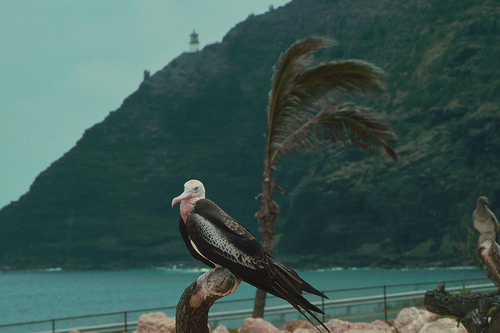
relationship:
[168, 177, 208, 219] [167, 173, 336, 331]
head on a bird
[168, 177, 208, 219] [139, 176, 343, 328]
head on top of bird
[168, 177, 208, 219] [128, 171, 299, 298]
head on top of bird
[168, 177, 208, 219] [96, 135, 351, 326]
head on top of bird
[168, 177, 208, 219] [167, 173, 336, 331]
head on top of bird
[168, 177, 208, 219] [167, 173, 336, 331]
head on bird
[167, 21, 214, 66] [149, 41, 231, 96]
lighthouse up on bluff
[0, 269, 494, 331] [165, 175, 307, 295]
water body behind bird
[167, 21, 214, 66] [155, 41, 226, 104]
lighthouse on cliff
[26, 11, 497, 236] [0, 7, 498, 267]
cliff covered in vegetation